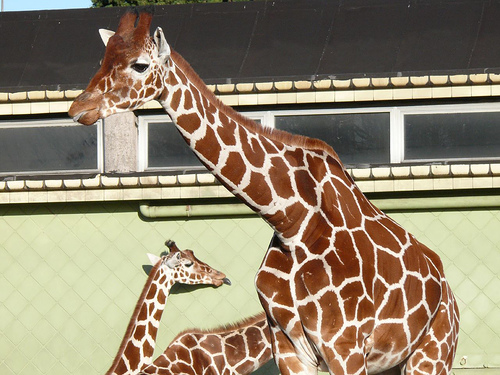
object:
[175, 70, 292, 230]
neck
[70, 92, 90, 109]
nose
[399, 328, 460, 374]
leg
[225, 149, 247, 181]
spot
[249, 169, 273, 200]
spot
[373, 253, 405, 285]
spot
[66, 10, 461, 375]
giraffe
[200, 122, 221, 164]
spot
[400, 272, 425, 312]
spot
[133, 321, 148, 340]
spot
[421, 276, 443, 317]
spot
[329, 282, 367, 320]
spot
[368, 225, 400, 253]
spot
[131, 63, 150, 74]
eye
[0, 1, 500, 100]
roof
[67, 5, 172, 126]
head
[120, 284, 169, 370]
neck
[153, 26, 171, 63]
ear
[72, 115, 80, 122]
tongue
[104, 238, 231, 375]
giraffe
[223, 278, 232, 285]
tongue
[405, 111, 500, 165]
window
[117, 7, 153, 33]
horns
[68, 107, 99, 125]
mouth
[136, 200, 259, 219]
pipe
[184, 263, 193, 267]
eye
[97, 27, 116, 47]
ear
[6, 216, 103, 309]
tile